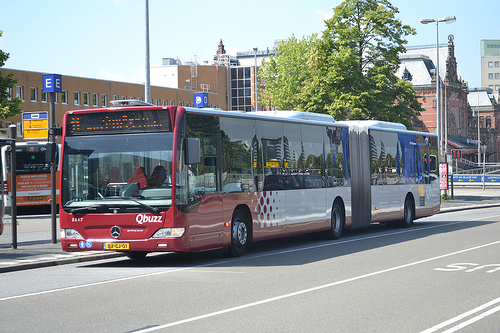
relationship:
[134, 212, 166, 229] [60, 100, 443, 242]
qbuzz on bus front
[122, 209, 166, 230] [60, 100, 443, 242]
word on bus front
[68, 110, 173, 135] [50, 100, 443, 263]
display on bus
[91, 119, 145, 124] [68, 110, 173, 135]
information on display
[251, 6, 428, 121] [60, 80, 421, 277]
green trees behind bus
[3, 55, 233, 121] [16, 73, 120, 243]
building near bus stop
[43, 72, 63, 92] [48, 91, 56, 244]
cube on pole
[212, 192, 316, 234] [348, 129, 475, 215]
design on bus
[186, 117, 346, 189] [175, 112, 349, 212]
reflection on window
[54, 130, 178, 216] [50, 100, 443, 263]
windshield on bus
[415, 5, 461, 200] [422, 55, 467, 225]
street lights on pole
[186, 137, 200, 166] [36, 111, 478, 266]
mirror on bus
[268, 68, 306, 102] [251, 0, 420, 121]
foliage on green trees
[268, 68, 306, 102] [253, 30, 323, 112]
foliage on tree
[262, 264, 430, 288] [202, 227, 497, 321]
stripes on road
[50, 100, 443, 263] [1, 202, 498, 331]
bus on street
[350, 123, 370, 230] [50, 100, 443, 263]
connecting piece on bus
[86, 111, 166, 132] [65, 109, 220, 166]
bus route on area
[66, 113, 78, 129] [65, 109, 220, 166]
number on area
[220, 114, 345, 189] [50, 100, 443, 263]
window on bus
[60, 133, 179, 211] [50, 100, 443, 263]
front window on bus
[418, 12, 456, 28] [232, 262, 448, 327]
lights on street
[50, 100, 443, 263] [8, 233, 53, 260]
bus next to sidewalk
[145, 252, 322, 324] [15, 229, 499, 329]
line on street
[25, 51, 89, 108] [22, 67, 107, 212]
sign attached pole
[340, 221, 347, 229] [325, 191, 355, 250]
part of wheel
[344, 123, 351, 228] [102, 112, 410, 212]
edge of bus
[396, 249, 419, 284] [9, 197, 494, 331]
part of road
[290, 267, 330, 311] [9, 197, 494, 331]
part of a road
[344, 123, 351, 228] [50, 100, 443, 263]
edge of a bus